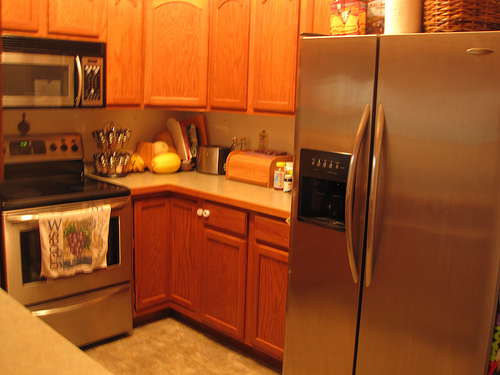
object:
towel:
[37, 204, 109, 278]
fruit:
[149, 152, 182, 174]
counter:
[95, 164, 293, 211]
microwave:
[0, 30, 107, 110]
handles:
[343, 105, 385, 286]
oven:
[0, 134, 128, 350]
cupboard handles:
[195, 209, 211, 219]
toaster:
[197, 143, 230, 176]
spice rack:
[93, 120, 133, 180]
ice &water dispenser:
[298, 144, 353, 230]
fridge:
[279, 31, 497, 374]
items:
[328, 1, 499, 36]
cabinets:
[1, 2, 359, 113]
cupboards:
[134, 195, 289, 360]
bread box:
[224, 151, 284, 189]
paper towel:
[383, 1, 424, 35]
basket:
[421, 0, 499, 32]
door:
[282, 33, 377, 375]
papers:
[167, 117, 208, 160]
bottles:
[273, 162, 286, 191]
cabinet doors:
[146, 2, 210, 112]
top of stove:
[2, 170, 129, 208]